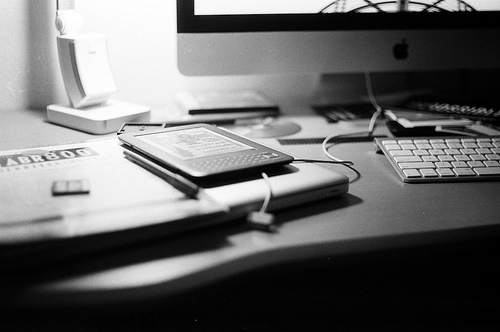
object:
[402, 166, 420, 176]
keys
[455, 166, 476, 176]
keys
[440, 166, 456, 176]
keys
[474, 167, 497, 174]
keys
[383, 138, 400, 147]
keys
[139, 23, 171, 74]
light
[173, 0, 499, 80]
monitor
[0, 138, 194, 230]
material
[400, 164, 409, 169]
number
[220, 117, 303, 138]
cd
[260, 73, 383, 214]
cord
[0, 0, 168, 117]
wall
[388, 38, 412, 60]
apple symbol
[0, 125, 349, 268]
laptop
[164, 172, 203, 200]
pen cap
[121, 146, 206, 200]
pen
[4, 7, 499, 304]
gadgets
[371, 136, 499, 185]
keyboard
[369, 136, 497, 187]
electronic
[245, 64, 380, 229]
charger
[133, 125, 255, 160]
screen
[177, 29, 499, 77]
white part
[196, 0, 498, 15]
screen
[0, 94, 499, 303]
desk top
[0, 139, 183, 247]
magazine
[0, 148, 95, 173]
writing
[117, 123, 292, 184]
e-reader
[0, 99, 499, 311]
table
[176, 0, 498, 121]
computer